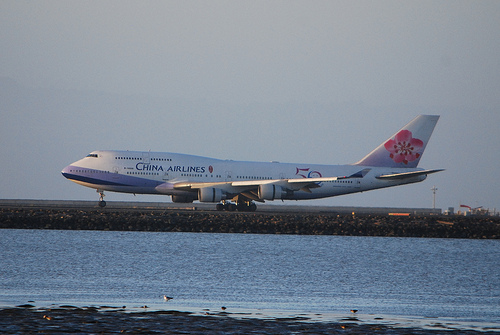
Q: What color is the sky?
A: Light grey.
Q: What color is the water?
A: Blue.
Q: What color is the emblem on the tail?
A: Red.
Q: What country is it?
A: China.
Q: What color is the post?
A: Silver.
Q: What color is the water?
A: Blue.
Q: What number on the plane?
A: 50.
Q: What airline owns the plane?
A: China airlines.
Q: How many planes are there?
A: One.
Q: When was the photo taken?
A: During the day.